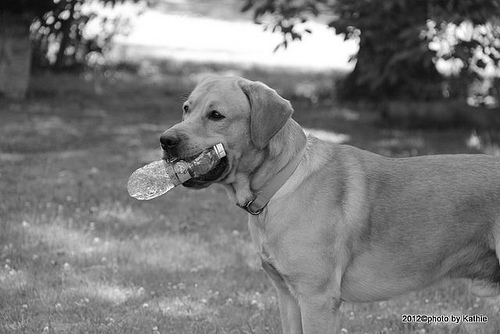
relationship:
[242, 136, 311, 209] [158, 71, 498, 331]
collar on dog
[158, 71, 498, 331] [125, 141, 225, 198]
dog carrying a bottle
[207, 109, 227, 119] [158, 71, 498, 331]
eye of dog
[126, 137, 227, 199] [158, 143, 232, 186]
bottle in mouth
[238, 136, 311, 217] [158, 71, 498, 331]
collar on dog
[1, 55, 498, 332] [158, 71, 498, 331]
grass under dog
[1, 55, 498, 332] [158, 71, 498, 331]
grass below dog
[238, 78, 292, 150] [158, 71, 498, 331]
ear on dog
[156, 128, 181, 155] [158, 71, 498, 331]
nose on dog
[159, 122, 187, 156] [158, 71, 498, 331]
snout on dog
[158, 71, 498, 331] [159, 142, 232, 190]
dog has mouth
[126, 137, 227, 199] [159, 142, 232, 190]
bottle in mouth